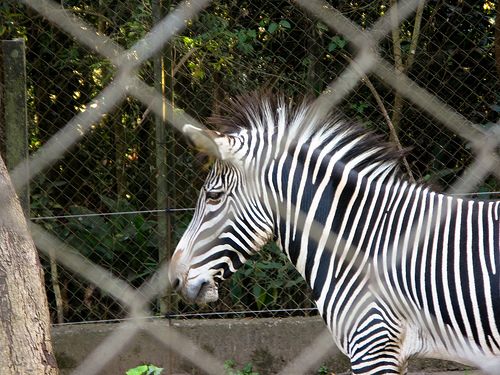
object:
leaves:
[267, 23, 278, 36]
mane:
[203, 82, 447, 194]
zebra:
[165, 89, 499, 374]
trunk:
[0, 157, 58, 374]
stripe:
[482, 202, 498, 334]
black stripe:
[444, 194, 476, 355]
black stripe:
[277, 139, 297, 254]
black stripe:
[189, 249, 246, 270]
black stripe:
[302, 160, 347, 290]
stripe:
[191, 238, 252, 262]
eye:
[200, 185, 228, 204]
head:
[164, 113, 322, 308]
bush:
[0, 0, 499, 319]